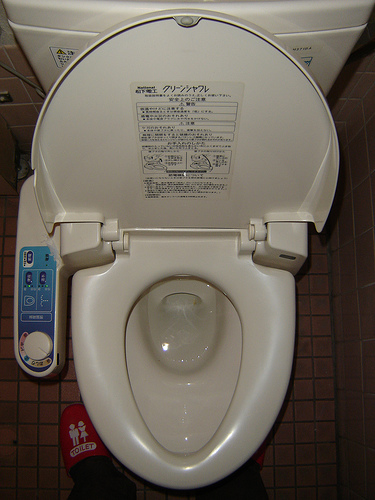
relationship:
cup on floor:
[55, 398, 112, 488] [2, 156, 374, 495]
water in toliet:
[167, 315, 191, 340] [2, 0, 357, 488]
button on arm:
[19, 328, 53, 361] [13, 175, 63, 382]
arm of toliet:
[13, 175, 63, 382] [2, 0, 357, 488]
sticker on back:
[132, 80, 245, 198] [26, 8, 342, 243]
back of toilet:
[26, 8, 342, 243] [0, 1, 373, 492]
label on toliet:
[48, 46, 81, 72] [2, 0, 357, 488]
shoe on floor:
[53, 400, 123, 498] [3, 195, 340, 498]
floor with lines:
[3, 380, 86, 498] [330, 275, 346, 498]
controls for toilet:
[16, 245, 57, 373] [0, 1, 373, 492]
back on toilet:
[26, 8, 342, 243] [30, 54, 308, 354]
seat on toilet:
[68, 230, 295, 490] [0, 1, 373, 492]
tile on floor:
[309, 353, 352, 455] [296, 293, 338, 494]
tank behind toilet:
[0, 0, 373, 117] [23, 20, 324, 437]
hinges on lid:
[100, 216, 267, 256] [79, 208, 301, 472]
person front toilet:
[54, 408, 310, 498] [88, 275, 279, 421]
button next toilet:
[19, 328, 53, 361] [11, 61, 360, 467]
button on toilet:
[24, 252, 30, 262] [7, 18, 323, 499]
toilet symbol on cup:
[65, 420, 96, 459] [46, 399, 117, 499]